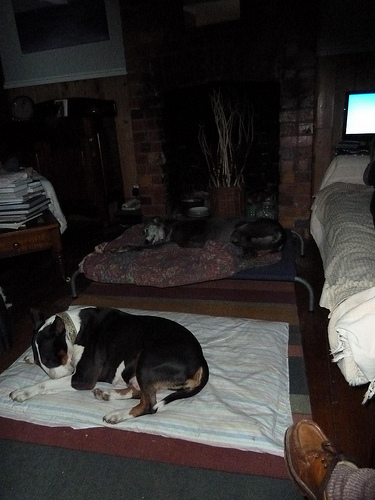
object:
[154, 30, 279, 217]
fireplace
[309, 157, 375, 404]
bed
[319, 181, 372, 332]
bedding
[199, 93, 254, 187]
tree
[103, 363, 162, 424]
back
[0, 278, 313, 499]
bed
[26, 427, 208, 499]
stripes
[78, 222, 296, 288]
dog bed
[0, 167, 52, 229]
books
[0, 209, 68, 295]
table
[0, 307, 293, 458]
blanket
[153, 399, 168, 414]
tip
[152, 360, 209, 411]
dog's tail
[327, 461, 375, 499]
sock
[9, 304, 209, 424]
dog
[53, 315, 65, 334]
ear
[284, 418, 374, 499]
person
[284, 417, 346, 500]
shoe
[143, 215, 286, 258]
dog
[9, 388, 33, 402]
paw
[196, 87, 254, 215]
decoration